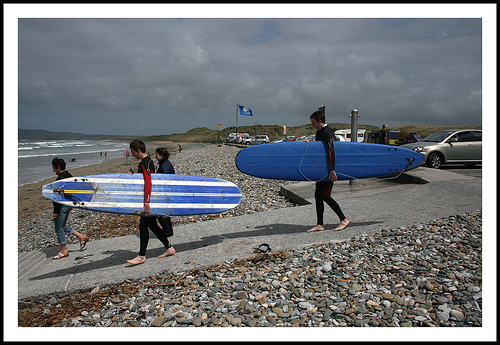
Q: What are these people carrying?
A: Surfboards.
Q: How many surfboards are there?
A: 2.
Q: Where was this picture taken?
A: The beach.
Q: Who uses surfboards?
A: Surfers.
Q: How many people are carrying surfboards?
A: 2.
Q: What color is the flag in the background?
A: Blue.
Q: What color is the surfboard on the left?
A: Blue and White.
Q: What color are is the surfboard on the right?
A: Blue.